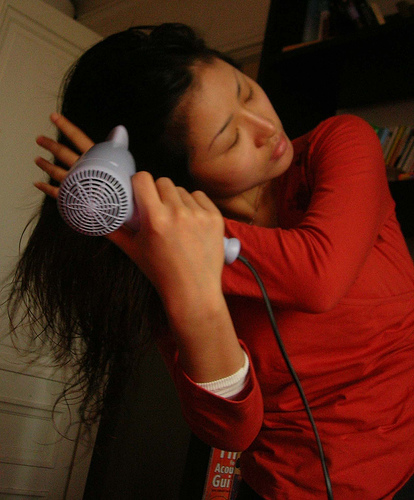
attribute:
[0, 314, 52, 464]
door — open, white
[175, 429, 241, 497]
book — red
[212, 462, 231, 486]
lettering — blue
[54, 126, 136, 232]
blow dryer — grey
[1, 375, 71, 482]
drawers — white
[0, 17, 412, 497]
lady — standing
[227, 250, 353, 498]
black cord — long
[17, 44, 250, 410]
hair — black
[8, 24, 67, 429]
door — bwhite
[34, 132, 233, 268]
hair dryer — gray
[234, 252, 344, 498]
cord — black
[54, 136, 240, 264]
hair dryer — grey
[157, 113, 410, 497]
shirt — red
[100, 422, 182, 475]
bookcase — black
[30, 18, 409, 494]
woman — standing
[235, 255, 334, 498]
cord — black, electrical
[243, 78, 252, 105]
eye — closed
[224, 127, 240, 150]
eye — closed